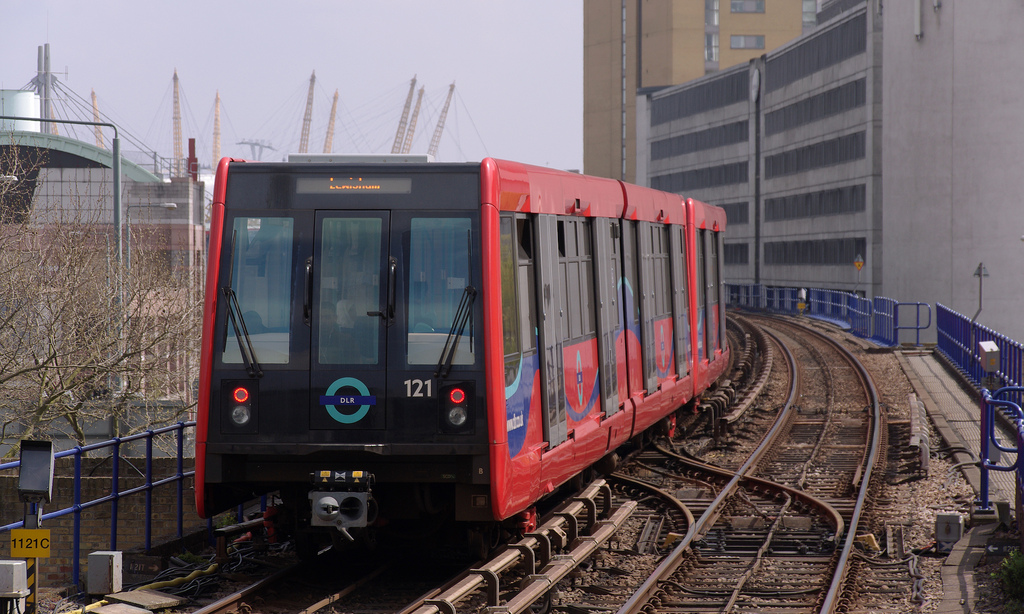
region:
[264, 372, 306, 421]
the train is black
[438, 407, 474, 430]
the light is off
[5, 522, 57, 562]
the sign is yellow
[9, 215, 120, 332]
the tree has no leaves on it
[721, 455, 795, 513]
the tracks are rusty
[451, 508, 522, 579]
the train is on the track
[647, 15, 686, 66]
the building is tan in color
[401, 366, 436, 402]
white number on train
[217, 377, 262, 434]
headlights on the train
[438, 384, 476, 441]
headlights on left side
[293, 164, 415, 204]
destination of the train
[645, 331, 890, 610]
brown train tracks on ground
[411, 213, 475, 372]
left front window on train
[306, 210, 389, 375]
middle window on train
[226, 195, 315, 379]
right side window on train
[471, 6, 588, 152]
blue sky in the air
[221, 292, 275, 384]
windshield wiper on train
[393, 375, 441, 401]
white number 121 on black background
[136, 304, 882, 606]
Railroad tracks with a curve in them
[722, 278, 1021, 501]
blue metal railing at the edge of the tracks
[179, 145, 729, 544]
red and black passenger train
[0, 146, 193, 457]
trees without any leaves on them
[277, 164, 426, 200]
changeable sign made of lights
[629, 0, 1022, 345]
gray building with slight curve to it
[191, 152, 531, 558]
front of a train with large windows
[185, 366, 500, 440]
headlights on the front of a vehicle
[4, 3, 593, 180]
overcast sky with no distinct clouds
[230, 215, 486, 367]
the front window on the train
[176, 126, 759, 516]
it is a red train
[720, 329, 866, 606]
it is the tracks of the train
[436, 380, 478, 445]
lights on the front of the train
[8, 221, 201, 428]
some trees without any leaves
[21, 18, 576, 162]
the sky is blue and clear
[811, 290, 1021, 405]
blue railing on the side of the tracks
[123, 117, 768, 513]
a large red train moving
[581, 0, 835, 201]
a brown building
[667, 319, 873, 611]
the tracks are brown